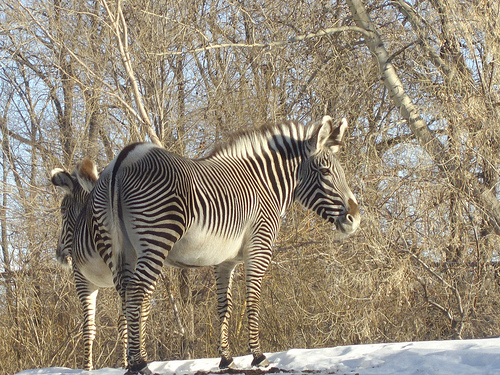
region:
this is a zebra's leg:
[246, 242, 270, 365]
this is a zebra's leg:
[210, 274, 244, 369]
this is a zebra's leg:
[127, 245, 159, 373]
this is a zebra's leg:
[71, 280, 106, 373]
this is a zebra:
[101, 102, 388, 370]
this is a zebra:
[49, 162, 154, 370]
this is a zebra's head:
[294, 101, 388, 265]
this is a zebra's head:
[45, 165, 78, 272]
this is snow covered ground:
[267, 341, 496, 373]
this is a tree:
[0, 48, 42, 373]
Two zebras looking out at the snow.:
[103, 321, 154, 368]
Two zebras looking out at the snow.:
[190, 152, 225, 227]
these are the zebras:
[17, 119, 377, 373]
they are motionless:
[54, 112, 364, 364]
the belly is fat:
[187, 185, 247, 262]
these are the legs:
[208, 262, 270, 363]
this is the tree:
[364, 10, 471, 100]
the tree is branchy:
[378, 27, 482, 124]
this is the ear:
[307, 115, 336, 154]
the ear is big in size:
[307, 115, 339, 152]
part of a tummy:
[206, 228, 237, 265]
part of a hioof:
[244, 328, 266, 355]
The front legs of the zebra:
[213, 265, 265, 362]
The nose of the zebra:
[345, 201, 360, 225]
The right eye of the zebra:
[320, 164, 331, 178]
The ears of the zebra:
[313, 114, 348, 151]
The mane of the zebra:
[217, 123, 317, 156]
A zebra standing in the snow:
[100, 116, 360, 374]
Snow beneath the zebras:
[23, 337, 497, 374]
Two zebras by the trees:
[49, 116, 359, 374]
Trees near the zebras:
[1, 2, 496, 374]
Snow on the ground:
[18, 337, 498, 374]